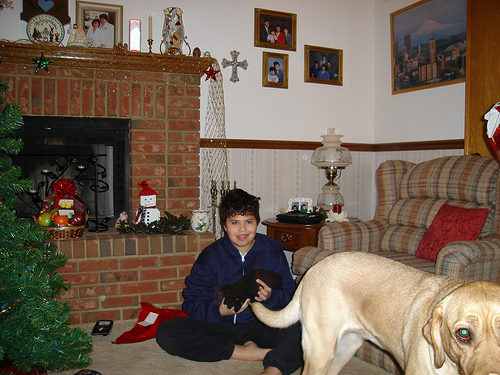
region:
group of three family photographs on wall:
[253, 8, 345, 90]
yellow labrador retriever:
[256, 249, 498, 373]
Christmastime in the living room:
[0, 0, 498, 374]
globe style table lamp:
[308, 130, 348, 211]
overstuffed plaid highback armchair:
[295, 153, 496, 371]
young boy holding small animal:
[155, 187, 300, 372]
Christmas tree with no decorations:
[0, 101, 91, 371]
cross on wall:
[222, 50, 247, 81]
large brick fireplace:
[1, 40, 211, 325]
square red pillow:
[416, 202, 486, 261]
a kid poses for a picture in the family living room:
[151, 182, 303, 374]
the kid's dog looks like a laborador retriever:
[246, 245, 499, 373]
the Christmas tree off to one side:
[2, 70, 99, 374]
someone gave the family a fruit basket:
[33, 173, 94, 240]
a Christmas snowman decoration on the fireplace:
[111, 175, 189, 235]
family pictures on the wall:
[248, 4, 347, 93]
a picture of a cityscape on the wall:
[387, 0, 464, 95]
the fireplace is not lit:
[3, 115, 129, 227]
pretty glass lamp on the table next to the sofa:
[306, 125, 356, 223]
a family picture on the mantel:
[69, 0, 127, 49]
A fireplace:
[11, 51, 207, 223]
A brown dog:
[265, 241, 495, 366]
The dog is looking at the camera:
[254, 260, 497, 363]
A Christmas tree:
[2, 107, 96, 363]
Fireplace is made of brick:
[2, 45, 219, 305]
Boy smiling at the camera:
[169, 181, 290, 351]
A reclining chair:
[300, 142, 498, 279]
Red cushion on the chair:
[414, 192, 485, 262]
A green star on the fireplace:
[30, 48, 55, 76]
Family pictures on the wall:
[250, 2, 360, 99]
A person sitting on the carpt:
[154, 163, 296, 373]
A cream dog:
[256, 244, 499, 371]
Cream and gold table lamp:
[305, 117, 356, 215]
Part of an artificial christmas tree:
[3, 94, 98, 372]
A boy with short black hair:
[202, 175, 274, 253]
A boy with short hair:
[207, 180, 269, 250]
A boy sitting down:
[156, 190, 316, 374]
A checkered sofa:
[372, 141, 497, 256]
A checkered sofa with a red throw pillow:
[367, 148, 499, 250]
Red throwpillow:
[414, 204, 494, 261]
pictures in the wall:
[250, 3, 359, 100]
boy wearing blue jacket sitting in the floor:
[160, 180, 304, 360]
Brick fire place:
[1, 39, 202, 319]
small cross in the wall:
[219, 43, 250, 93]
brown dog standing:
[279, 243, 498, 373]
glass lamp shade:
[311, 125, 352, 215]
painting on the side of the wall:
[389, 0, 481, 108]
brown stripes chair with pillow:
[347, 143, 498, 288]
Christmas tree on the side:
[1, 98, 83, 373]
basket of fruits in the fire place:
[33, 169, 93, 229]